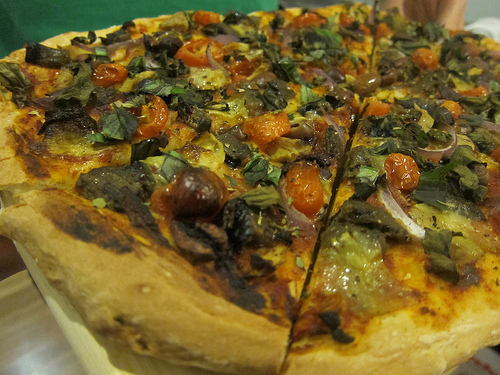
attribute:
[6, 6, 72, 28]
cross — not visible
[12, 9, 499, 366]
pizza — burnt, cut, sliced, large, vegetarian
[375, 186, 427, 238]
onions — red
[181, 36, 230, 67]
tomatoes — red, small, cherry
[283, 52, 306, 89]
vegetable — green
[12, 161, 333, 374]
crust — golden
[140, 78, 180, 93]
kale — green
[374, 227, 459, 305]
cheese — yellow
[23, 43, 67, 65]
mushroom — brown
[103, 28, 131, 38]
mushroom — sliced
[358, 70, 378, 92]
olive — green